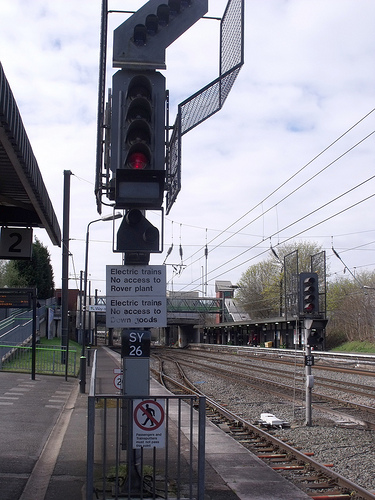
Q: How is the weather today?
A: It is cloudy.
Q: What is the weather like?
A: It is cloudy.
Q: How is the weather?
A: It is cloudy.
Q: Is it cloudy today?
A: Yes, it is cloudy.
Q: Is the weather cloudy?
A: Yes, it is cloudy.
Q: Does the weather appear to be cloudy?
A: Yes, it is cloudy.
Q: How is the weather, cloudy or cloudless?
A: It is cloudy.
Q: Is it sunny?
A: No, it is cloudy.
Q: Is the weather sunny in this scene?
A: No, it is cloudy.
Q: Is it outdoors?
A: Yes, it is outdoors.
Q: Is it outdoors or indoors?
A: It is outdoors.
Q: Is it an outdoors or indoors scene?
A: It is outdoors.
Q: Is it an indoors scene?
A: No, it is outdoors.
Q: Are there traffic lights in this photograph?
A: Yes, there is a traffic light.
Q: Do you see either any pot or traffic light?
A: Yes, there is a traffic light.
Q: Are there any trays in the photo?
A: No, there are no trays.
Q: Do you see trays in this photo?
A: No, there are no trays.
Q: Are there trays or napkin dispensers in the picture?
A: No, there are no trays or napkin dispensers.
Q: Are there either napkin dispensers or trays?
A: No, there are no trays or napkin dispensers.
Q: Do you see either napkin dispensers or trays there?
A: No, there are no trays or napkin dispensers.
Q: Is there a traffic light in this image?
A: Yes, there is a traffic light.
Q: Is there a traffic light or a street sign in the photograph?
A: Yes, there is a traffic light.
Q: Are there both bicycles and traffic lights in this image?
A: No, there is a traffic light but no bicycles.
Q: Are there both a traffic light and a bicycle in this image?
A: No, there is a traffic light but no bicycles.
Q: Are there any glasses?
A: No, there are no glasses.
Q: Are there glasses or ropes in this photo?
A: No, there are no glasses or ropes.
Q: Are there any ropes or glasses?
A: No, there are no glasses or ropes.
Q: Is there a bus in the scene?
A: No, there are no buses.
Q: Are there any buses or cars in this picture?
A: No, there are no buses or cars.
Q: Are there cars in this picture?
A: No, there are no cars.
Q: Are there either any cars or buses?
A: No, there are no cars or buses.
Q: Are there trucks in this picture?
A: No, there are no trucks.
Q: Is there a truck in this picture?
A: No, there are no trucks.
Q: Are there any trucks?
A: No, there are no trucks.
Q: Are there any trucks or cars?
A: No, there are no trucks or cars.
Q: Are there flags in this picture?
A: No, there are no flags.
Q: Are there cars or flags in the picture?
A: No, there are no flags or cars.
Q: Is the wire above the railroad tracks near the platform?
A: Yes, the wire is above the tracks.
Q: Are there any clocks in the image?
A: No, there are no clocks.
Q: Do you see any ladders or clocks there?
A: No, there are no clocks or ladders.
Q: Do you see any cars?
A: No, there are no cars.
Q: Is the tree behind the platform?
A: Yes, the tree is behind the platform.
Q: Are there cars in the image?
A: No, there are no cars.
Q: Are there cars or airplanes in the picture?
A: No, there are no cars or airplanes.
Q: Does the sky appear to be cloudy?
A: Yes, the sky is cloudy.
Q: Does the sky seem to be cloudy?
A: Yes, the sky is cloudy.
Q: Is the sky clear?
A: No, the sky is cloudy.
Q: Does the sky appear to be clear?
A: No, the sky is cloudy.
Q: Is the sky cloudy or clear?
A: The sky is cloudy.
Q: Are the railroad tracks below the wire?
A: Yes, the railroad tracks are below the wire.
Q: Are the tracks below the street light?
A: Yes, the tracks are below the street light.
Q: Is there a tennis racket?
A: No, there are no rackets.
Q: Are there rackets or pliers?
A: No, there are no rackets or pliers.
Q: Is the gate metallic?
A: Yes, the gate is metallic.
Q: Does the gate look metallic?
A: Yes, the gate is metallic.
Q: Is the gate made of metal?
A: Yes, the gate is made of metal.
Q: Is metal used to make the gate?
A: Yes, the gate is made of metal.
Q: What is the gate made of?
A: The gate is made of metal.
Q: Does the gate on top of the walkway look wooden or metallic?
A: The gate is metallic.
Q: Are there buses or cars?
A: No, there are no cars or buses.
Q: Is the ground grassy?
A: Yes, the ground is grassy.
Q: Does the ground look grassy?
A: Yes, the ground is grassy.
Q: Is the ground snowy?
A: No, the ground is grassy.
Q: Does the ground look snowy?
A: No, the ground is grassy.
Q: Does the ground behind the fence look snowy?
A: No, the ground is grassy.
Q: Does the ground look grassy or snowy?
A: The ground is grassy.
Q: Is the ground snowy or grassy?
A: The ground is grassy.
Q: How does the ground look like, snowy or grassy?
A: The ground is grassy.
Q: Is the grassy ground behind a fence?
A: Yes, the ground is behind a fence.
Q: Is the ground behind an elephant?
A: No, the ground is behind a fence.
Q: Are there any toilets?
A: No, there are no toilets.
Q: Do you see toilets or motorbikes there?
A: No, there are no toilets or motorbikes.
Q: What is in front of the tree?
A: The platform is in front of the tree.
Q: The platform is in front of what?
A: The platform is in front of the tree.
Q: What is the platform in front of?
A: The platform is in front of the tree.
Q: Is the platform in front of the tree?
A: Yes, the platform is in front of the tree.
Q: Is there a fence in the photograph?
A: Yes, there is a fence.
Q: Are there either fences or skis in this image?
A: Yes, there is a fence.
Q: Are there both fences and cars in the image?
A: No, there is a fence but no cars.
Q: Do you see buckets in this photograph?
A: No, there are no buckets.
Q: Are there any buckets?
A: No, there are no buckets.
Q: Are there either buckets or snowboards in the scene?
A: No, there are no buckets or snowboards.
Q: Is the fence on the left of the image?
A: Yes, the fence is on the left of the image.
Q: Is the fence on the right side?
A: No, the fence is on the left of the image.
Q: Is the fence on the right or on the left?
A: The fence is on the left of the image.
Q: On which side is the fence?
A: The fence is on the left of the image.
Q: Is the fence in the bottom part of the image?
A: Yes, the fence is in the bottom of the image.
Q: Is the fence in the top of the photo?
A: No, the fence is in the bottom of the image.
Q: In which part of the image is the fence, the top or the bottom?
A: The fence is in the bottom of the image.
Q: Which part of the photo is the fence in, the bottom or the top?
A: The fence is in the bottom of the image.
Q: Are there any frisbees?
A: No, there are no frisbees.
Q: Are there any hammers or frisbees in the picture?
A: No, there are no frisbees or hammers.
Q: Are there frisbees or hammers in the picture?
A: No, there are no frisbees or hammers.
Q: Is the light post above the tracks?
A: Yes, the light post is above the tracks.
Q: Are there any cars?
A: No, there are no cars.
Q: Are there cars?
A: No, there are no cars.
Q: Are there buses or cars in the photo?
A: No, there are no cars or buses.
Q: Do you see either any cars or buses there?
A: No, there are no cars or buses.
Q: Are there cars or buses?
A: No, there are no cars or buses.